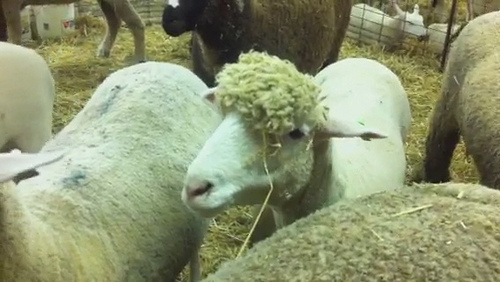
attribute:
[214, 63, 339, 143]
sheep —      a sheep,       puff, sheared, black, laying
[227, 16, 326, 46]
brown —  unsheared